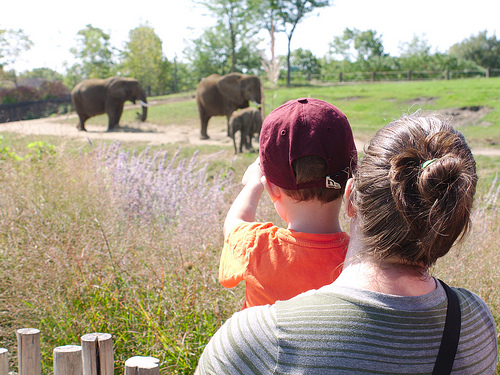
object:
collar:
[275, 228, 351, 249]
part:
[136, 364, 157, 375]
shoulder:
[431, 274, 484, 300]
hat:
[257, 96, 358, 191]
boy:
[216, 97, 357, 311]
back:
[265, 287, 499, 375]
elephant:
[70, 76, 150, 131]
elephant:
[229, 107, 263, 155]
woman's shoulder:
[222, 283, 344, 336]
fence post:
[80, 332, 114, 375]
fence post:
[15, 327, 38, 375]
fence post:
[51, 345, 81, 375]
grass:
[0, 137, 499, 375]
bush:
[0, 136, 243, 375]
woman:
[191, 111, 500, 375]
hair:
[351, 109, 478, 263]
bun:
[389, 132, 479, 236]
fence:
[0, 327, 161, 375]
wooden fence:
[279, 67, 500, 84]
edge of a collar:
[285, 228, 348, 236]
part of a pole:
[79, 331, 113, 374]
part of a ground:
[113, 141, 215, 171]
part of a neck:
[331, 254, 435, 296]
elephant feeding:
[71, 76, 149, 133]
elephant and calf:
[195, 72, 263, 155]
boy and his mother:
[189, 97, 499, 375]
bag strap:
[430, 278, 464, 375]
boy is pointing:
[222, 156, 265, 267]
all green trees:
[259, 0, 336, 86]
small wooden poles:
[0, 348, 11, 374]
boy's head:
[258, 96, 359, 223]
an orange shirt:
[218, 222, 351, 311]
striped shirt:
[191, 275, 500, 375]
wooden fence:
[0, 95, 74, 126]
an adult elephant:
[195, 72, 264, 140]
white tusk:
[136, 100, 150, 108]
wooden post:
[371, 71, 375, 84]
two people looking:
[193, 97, 498, 375]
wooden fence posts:
[370, 71, 374, 83]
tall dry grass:
[92, 142, 241, 312]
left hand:
[222, 180, 262, 251]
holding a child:
[189, 98, 498, 375]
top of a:
[13, 327, 41, 336]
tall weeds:
[0, 156, 104, 306]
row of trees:
[121, 22, 163, 96]